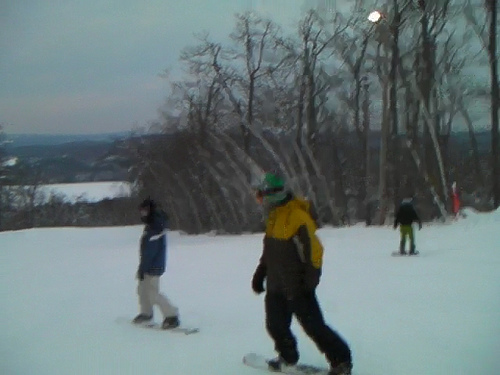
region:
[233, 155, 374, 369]
Person on skis.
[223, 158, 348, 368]
Skier with yellow and black jacket.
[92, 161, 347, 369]
Snowboarders on the snow.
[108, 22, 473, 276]
Trees behind the snowboarders.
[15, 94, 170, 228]
Mountains behind the trees.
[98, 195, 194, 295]
Man in white and blue jacket.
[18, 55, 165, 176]
Blue sky above the mountains.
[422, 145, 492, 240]
orange sign by the trees.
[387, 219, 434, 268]
Green pants on the man.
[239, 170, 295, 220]
Green helmet on the man.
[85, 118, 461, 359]
snowboarders active in evening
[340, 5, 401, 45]
moon shining through the trees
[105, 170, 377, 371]
snowboarders leading with right leg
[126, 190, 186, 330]
white stripe across white jacket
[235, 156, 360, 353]
yellow and black jacket with black pants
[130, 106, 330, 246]
trees curving to one side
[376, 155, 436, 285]
snowboarder moving toward trees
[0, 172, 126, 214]
large area of snow beyond the trees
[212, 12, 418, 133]
dark trees reaching straight up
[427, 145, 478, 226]
person in red behind tree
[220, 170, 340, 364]
this is a man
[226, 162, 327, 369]
the man is snow skating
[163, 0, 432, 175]
the tree are dry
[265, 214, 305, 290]
the jacket is yellow and black in color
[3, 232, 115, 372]
the place is full of snow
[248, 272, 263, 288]
he is wearing black glove on his hand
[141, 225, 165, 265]
this man the man is wearing blue jackets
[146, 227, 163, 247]
the jacket has white strip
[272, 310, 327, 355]
the legs are wide apart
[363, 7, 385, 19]
the light is on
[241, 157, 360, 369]
a person skating in ice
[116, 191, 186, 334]
a person skating in ice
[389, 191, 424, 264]
a person skating in ice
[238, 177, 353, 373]
a person wearing a jacket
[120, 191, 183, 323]
a person wearing a jacket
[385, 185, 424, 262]
a person wearing a jacket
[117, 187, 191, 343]
a person wearing a hat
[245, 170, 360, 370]
a person wearing a hat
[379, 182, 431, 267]
a person wearing a hat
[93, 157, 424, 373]
people skating on ice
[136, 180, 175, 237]
Man wearing black ski mask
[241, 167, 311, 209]
Man wearing a green ski mask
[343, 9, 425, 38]
Light on top of a pole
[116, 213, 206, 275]
Man wearing a blue jacket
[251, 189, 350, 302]
Man wearing jacket with yellow top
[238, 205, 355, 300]
Man wearing ski jacket with black bottom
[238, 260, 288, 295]
Man wearing a ski glove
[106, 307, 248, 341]
Man in white pants on snow board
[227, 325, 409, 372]
Man in black pants on snow board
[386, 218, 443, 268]
Man wearing green pants on snow board